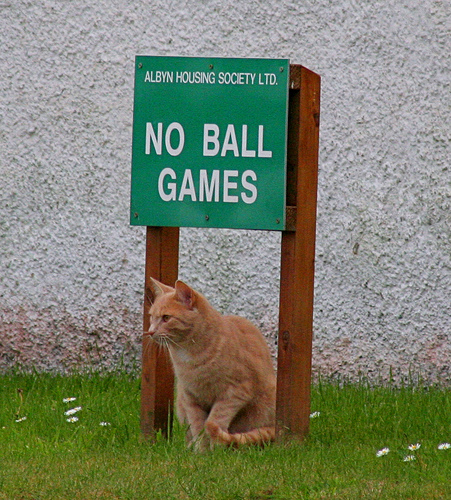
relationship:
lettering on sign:
[154, 166, 257, 209] [127, 54, 291, 231]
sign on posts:
[127, 54, 291, 231] [137, 65, 323, 438]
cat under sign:
[138, 262, 288, 456] [127, 54, 291, 231]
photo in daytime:
[13, 14, 437, 479] [8, 0, 435, 471]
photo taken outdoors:
[13, 14, 437, 479] [2, 2, 447, 497]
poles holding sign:
[121, 40, 324, 454] [119, 45, 291, 240]